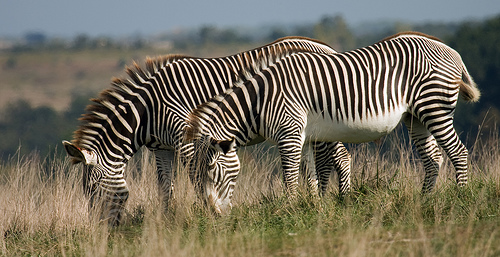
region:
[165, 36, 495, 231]
This is a zebra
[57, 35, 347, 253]
This is a zebra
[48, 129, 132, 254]
Head of a zebra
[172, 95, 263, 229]
Head of a zebra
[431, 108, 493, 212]
Leg of a zebra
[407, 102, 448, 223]
Leg of a zebra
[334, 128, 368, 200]
Leg of a zebra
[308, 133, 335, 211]
Leg of a zebra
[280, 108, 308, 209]
Leg of a zebra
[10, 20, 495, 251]
Zebras grazing in field of savannah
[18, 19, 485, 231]
Wild African territory with zebras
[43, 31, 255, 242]
Bowing heads of feeding zebras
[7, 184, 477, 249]
Grass being eaten by large zebras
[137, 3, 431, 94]
Arched backs of zebras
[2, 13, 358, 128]
Blurred landscape of savannah in distance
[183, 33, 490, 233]
Zebra content eating brown tall grass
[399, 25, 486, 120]
Tail flapping while eating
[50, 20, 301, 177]
Hairy frills of eating zebras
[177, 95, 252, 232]
Head of lethargic zebra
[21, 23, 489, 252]
Zebras grazing in field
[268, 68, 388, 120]
Stripes on adult zebra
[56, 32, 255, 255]
Two zebra heads bowing to eat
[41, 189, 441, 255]
Brown tall grass on savannah and zebra snouts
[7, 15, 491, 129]
Blurred background of savannah with zebra tops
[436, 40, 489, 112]
Zebra tail behind pair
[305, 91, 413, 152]
Pudgy belly from grazing zebra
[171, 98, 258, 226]
Head of feeding zebra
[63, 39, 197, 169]
Frill of hair on zebra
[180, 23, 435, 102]
Arches on backs of zebras